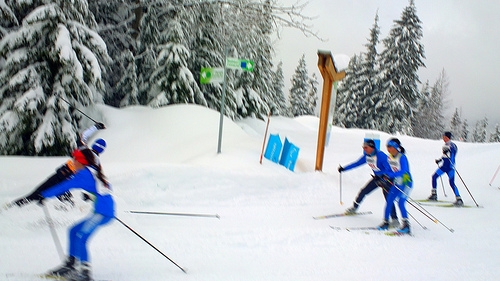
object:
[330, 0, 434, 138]
tree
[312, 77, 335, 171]
sign post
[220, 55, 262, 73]
sign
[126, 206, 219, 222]
pole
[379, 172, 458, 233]
pole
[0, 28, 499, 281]
snow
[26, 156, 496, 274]
slope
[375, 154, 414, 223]
ski suit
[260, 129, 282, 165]
flag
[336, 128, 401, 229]
skiers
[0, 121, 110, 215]
man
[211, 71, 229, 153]
post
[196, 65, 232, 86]
signs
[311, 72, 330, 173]
post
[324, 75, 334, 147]
hanging sign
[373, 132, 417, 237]
skiier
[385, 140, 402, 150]
blue head band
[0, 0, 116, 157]
pine tree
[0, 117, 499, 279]
progress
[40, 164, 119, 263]
jump suits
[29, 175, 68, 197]
black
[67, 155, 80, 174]
vest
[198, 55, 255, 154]
directional signs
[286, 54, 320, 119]
trees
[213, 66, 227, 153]
pole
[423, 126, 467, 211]
person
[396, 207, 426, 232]
ski poles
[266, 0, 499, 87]
sky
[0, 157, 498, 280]
snow skis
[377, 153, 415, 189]
blue coat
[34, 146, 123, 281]
person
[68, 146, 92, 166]
red headband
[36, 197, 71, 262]
ski poles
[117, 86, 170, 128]
ski in air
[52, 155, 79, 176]
orange and black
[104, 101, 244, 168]
mound